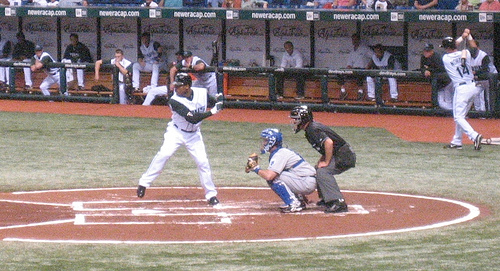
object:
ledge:
[12, 8, 492, 40]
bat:
[211, 41, 228, 111]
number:
[454, 62, 468, 77]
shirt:
[440, 48, 485, 85]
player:
[29, 44, 69, 92]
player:
[95, 48, 135, 101]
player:
[132, 31, 162, 93]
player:
[364, 41, 404, 104]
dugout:
[2, 13, 499, 112]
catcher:
[243, 128, 320, 216]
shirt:
[299, 120, 345, 158]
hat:
[171, 68, 194, 88]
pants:
[315, 148, 355, 202]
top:
[164, 88, 213, 122]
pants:
[134, 120, 218, 202]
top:
[441, 49, 491, 84]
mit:
[242, 141, 279, 211]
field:
[0, 72, 499, 270]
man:
[273, 37, 312, 101]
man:
[349, 28, 401, 104]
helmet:
[285, 103, 312, 133]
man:
[277, 84, 391, 252]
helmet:
[170, 72, 195, 92]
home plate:
[131, 206, 166, 218]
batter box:
[74, 212, 231, 226]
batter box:
[72, 198, 224, 215]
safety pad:
[270, 179, 291, 208]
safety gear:
[286, 102, 312, 135]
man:
[131, 72, 224, 206]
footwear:
[207, 194, 219, 206]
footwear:
[135, 185, 147, 200]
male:
[439, 25, 484, 154]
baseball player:
[136, 73, 225, 201]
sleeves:
[168, 93, 220, 123]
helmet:
[259, 127, 280, 153]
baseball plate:
[134, 207, 165, 217]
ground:
[3, 96, 497, 267]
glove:
[245, 154, 261, 174]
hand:
[250, 159, 257, 168]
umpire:
[293, 106, 355, 215]